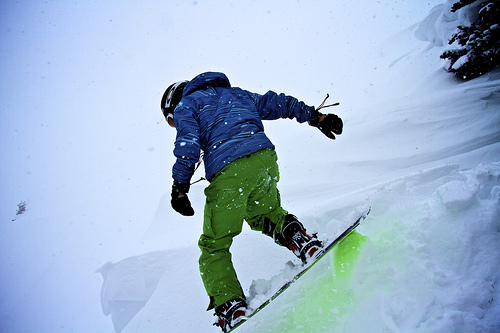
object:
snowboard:
[221, 206, 373, 333]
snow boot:
[275, 214, 324, 261]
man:
[161, 72, 341, 332]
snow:
[290, 84, 499, 333]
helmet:
[162, 79, 189, 127]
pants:
[197, 146, 285, 307]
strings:
[316, 93, 329, 110]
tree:
[438, 0, 500, 82]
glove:
[313, 111, 343, 140]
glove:
[171, 182, 195, 216]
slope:
[100, 0, 499, 333]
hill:
[93, 0, 500, 333]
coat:
[172, 72, 312, 180]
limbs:
[440, 48, 468, 58]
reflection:
[278, 232, 366, 333]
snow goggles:
[166, 113, 174, 127]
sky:
[0, 0, 382, 333]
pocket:
[203, 206, 216, 236]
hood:
[182, 71, 230, 97]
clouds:
[1, 0, 159, 115]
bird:
[15, 200, 25, 215]